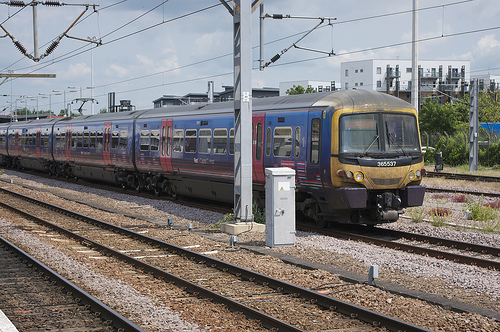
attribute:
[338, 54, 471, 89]
building — large, white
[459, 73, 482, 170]
pole — gray, electric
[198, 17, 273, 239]
pole — gray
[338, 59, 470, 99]
building — gray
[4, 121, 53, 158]
rear wagon — red, blue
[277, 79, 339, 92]
white building — large